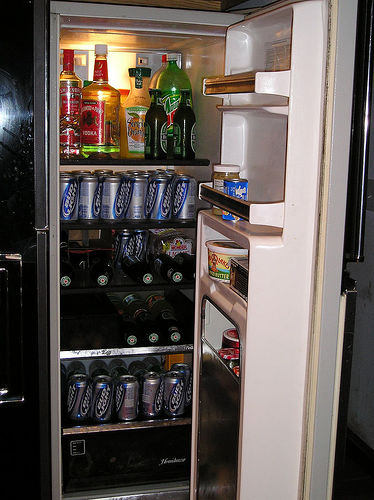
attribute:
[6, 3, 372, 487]
refrigerator — here, white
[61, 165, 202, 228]
beer cans — blue, here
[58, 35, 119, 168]
vodka bottles — big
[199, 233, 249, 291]
margarine tub — here, red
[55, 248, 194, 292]
beer bottles — here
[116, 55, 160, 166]
orange juice bottle — here, simply orange, large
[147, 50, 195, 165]
soda bottle — here, two liter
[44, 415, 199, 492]
crisper drawer — here, black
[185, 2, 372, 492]
door — open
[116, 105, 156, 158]
label — orange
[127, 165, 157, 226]
can — silver blue, whit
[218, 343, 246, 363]
lid — red, white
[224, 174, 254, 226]
container — blue, white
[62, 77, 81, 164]
label — red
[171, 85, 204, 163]
bottle — dark green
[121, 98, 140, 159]
liquid — yellow